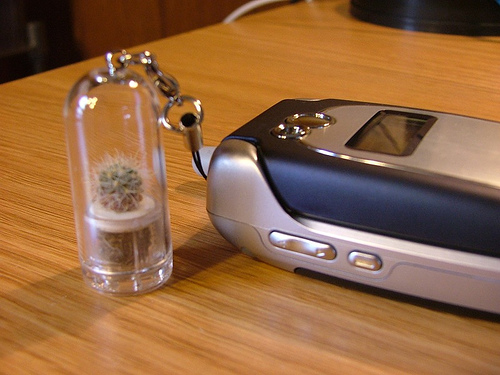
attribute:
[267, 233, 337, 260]
button — control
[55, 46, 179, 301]
holder — glass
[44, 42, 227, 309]
keychain — mini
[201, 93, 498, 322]
cellphone — silver, blue, flip-type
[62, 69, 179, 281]
terrarium — mini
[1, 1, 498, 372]
table — brown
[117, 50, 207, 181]
strap — cellphone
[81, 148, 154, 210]
ball — white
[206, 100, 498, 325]
cell phone — keychain, decoration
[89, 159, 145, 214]
cactus — mini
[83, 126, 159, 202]
thorns — little